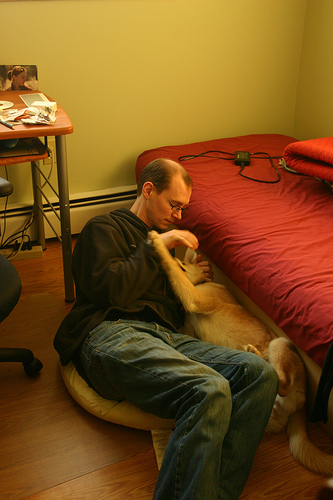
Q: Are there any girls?
A: No, there are no girls.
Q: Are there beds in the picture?
A: Yes, there is a bed.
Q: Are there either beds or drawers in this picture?
A: Yes, there is a bed.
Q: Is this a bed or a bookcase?
A: This is a bed.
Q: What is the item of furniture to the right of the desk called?
A: The piece of furniture is a bed.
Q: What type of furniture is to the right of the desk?
A: The piece of furniture is a bed.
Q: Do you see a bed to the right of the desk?
A: Yes, there is a bed to the right of the desk.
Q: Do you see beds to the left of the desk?
A: No, the bed is to the right of the desk.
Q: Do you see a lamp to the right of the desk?
A: No, there is a bed to the right of the desk.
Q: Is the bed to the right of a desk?
A: Yes, the bed is to the right of a desk.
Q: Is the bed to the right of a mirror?
A: No, the bed is to the right of a desk.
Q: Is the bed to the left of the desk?
A: No, the bed is to the right of the desk.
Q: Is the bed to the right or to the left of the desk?
A: The bed is to the right of the desk.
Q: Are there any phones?
A: No, there are no phones.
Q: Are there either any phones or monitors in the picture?
A: No, there are no phones or monitors.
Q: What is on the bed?
A: The charger is on the bed.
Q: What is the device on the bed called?
A: The device is a charger.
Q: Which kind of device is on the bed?
A: The device is a charger.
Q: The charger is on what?
A: The charger is on the bed.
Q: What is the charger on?
A: The charger is on the bed.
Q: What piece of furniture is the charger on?
A: The charger is on the bed.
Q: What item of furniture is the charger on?
A: The charger is on the bed.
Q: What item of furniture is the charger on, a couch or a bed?
A: The charger is on a bed.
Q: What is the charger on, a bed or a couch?
A: The charger is on a bed.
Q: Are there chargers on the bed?
A: Yes, there is a charger on the bed.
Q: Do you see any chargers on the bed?
A: Yes, there is a charger on the bed.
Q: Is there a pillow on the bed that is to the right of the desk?
A: No, there is a charger on the bed.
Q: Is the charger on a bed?
A: Yes, the charger is on a bed.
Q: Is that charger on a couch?
A: No, the charger is on a bed.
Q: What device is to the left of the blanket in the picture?
A: The device is a charger.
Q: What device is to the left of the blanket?
A: The device is a charger.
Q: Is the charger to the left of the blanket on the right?
A: Yes, the charger is to the left of the blanket.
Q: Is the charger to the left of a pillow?
A: No, the charger is to the left of the blanket.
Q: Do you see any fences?
A: No, there are no fences.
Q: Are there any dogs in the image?
A: Yes, there is a dog.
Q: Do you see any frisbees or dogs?
A: Yes, there is a dog.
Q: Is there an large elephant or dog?
A: Yes, there is a large dog.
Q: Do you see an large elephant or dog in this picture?
A: Yes, there is a large dog.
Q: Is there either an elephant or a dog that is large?
A: Yes, the dog is large.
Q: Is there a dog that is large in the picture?
A: Yes, there is a large dog.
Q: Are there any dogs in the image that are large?
A: Yes, there is a dog that is large.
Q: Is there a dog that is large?
A: Yes, there is a dog that is large.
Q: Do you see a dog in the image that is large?
A: Yes, there is a dog that is large.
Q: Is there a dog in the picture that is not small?
A: Yes, there is a large dog.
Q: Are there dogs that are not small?
A: Yes, there is a large dog.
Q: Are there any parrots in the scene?
A: No, there are no parrots.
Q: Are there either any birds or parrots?
A: No, there are no parrots or birds.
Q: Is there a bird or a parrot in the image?
A: No, there are no parrots or birds.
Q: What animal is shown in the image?
A: The animal is a dog.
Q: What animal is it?
A: The animal is a dog.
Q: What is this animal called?
A: This is a dog.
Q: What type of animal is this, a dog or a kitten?
A: This is a dog.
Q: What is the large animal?
A: The animal is a dog.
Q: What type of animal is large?
A: The animal is a dog.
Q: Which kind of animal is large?
A: The animal is a dog.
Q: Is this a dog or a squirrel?
A: This is a dog.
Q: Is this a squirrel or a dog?
A: This is a dog.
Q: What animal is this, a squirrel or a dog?
A: This is a dog.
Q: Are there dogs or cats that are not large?
A: No, there is a dog but it is large.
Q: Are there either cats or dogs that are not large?
A: No, there is a dog but it is large.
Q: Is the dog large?
A: Yes, the dog is large.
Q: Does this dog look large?
A: Yes, the dog is large.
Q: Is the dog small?
A: No, the dog is large.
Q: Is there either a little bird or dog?
A: No, there is a dog but it is large.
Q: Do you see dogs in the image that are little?
A: No, there is a dog but it is large.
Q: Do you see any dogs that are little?
A: No, there is a dog but it is large.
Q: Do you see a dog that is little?
A: No, there is a dog but it is large.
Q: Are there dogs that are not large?
A: No, there is a dog but it is large.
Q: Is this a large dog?
A: Yes, this is a large dog.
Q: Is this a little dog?
A: No, this is a large dog.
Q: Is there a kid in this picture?
A: No, there are no children.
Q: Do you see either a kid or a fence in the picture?
A: No, there are no children or fences.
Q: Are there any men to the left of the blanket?
A: Yes, there is a man to the left of the blanket.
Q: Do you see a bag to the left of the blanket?
A: No, there is a man to the left of the blanket.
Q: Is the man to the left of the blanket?
A: Yes, the man is to the left of the blanket.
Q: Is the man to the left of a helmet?
A: No, the man is to the left of the blanket.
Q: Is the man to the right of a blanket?
A: No, the man is to the left of a blanket.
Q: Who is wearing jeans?
A: The man is wearing jeans.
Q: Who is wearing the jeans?
A: The man is wearing jeans.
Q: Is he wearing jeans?
A: Yes, the man is wearing jeans.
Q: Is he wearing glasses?
A: No, the man is wearing jeans.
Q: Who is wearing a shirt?
A: The man is wearing a shirt.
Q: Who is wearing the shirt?
A: The man is wearing a shirt.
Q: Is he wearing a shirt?
A: Yes, the man is wearing a shirt.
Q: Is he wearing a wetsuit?
A: No, the man is wearing a shirt.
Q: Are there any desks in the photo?
A: Yes, there is a desk.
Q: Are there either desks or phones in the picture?
A: Yes, there is a desk.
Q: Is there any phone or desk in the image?
A: Yes, there is a desk.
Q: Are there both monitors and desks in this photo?
A: No, there is a desk but no monitors.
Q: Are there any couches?
A: No, there are no couches.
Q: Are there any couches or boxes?
A: No, there are no couches or boxes.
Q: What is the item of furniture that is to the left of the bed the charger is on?
A: The piece of furniture is a desk.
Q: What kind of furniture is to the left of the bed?
A: The piece of furniture is a desk.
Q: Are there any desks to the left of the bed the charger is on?
A: Yes, there is a desk to the left of the bed.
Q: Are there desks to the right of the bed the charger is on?
A: No, the desk is to the left of the bed.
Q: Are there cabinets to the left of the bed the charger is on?
A: No, there is a desk to the left of the bed.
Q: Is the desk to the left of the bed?
A: Yes, the desk is to the left of the bed.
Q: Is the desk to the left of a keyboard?
A: No, the desk is to the left of the bed.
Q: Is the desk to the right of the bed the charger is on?
A: No, the desk is to the left of the bed.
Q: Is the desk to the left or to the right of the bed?
A: The desk is to the left of the bed.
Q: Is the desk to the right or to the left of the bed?
A: The desk is to the left of the bed.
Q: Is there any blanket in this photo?
A: Yes, there is a blanket.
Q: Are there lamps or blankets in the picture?
A: Yes, there is a blanket.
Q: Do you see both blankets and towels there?
A: No, there is a blanket but no towels.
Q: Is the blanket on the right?
A: Yes, the blanket is on the right of the image.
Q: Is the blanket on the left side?
A: No, the blanket is on the right of the image.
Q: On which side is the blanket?
A: The blanket is on the right of the image.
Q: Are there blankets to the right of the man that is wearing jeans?
A: Yes, there is a blanket to the right of the man.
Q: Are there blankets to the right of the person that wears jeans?
A: Yes, there is a blanket to the right of the man.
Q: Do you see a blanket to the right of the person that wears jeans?
A: Yes, there is a blanket to the right of the man.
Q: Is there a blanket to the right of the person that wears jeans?
A: Yes, there is a blanket to the right of the man.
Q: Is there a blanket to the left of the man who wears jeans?
A: No, the blanket is to the right of the man.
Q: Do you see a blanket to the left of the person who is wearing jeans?
A: No, the blanket is to the right of the man.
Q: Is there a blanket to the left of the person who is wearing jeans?
A: No, the blanket is to the right of the man.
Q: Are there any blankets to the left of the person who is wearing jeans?
A: No, the blanket is to the right of the man.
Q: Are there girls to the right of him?
A: No, there is a blanket to the right of the man.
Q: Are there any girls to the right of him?
A: No, there is a blanket to the right of the man.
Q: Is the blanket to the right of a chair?
A: No, the blanket is to the right of the man.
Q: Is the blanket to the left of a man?
A: No, the blanket is to the right of a man.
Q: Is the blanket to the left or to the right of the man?
A: The blanket is to the right of the man.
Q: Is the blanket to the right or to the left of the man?
A: The blanket is to the right of the man.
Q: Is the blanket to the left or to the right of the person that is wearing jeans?
A: The blanket is to the right of the man.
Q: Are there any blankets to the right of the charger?
A: Yes, there is a blanket to the right of the charger.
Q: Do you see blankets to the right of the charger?
A: Yes, there is a blanket to the right of the charger.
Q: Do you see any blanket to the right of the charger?
A: Yes, there is a blanket to the right of the charger.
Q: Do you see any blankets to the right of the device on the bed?
A: Yes, there is a blanket to the right of the charger.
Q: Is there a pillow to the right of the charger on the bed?
A: No, there is a blanket to the right of the charger.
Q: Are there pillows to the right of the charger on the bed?
A: No, there is a blanket to the right of the charger.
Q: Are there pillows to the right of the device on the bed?
A: No, there is a blanket to the right of the charger.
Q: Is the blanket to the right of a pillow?
A: No, the blanket is to the right of the charger.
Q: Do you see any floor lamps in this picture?
A: No, there are no floor lamps.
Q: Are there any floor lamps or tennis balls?
A: No, there are no floor lamps or tennis balls.